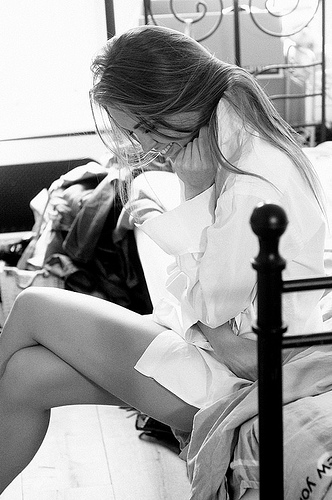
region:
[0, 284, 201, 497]
A woman's sexy legs crossed left over right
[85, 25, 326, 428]
Pretty woman sitting on bed looking down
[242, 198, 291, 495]
Black colored tubular bed post.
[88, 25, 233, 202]
Woman smiling while resting her hand on her face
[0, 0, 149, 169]
Bright outdoor light coming in through the window.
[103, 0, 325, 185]
Decorative frame of the bed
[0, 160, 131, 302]
Bunch of clothes lay in a heap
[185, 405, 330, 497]
New York printed bed sheets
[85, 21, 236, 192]
Lady with her hair falling onto her face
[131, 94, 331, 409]
Crisp white cotton button down shirt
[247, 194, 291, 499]
black metal post on the bed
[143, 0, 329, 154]
metal head board on the bed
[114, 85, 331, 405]
white shirt on the woman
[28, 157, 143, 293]
a basket full of clothes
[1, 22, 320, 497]
a woman sitting on the bed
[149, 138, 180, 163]
a smile on the woman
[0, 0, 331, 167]
windows next to the bed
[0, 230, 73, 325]
wicker basket full of clothes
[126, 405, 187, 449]
shoes next to the bed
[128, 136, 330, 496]
bed with white sheets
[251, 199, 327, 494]
bed is black metal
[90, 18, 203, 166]
woman is smiling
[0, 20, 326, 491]
woman is sittig on the bed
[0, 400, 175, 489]
floor is woden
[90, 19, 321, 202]
woman has long hair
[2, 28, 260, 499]
woman is caucasian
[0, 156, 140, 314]
pile of clothes spilling out clothes basket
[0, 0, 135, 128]
window letting bright light in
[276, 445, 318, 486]
New York on sheets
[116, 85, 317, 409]
woman wearing man's white shirt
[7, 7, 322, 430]
the picture is black and white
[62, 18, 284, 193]
the woman`s head is down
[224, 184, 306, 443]
the bed post is black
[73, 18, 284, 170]
the woman`s hair is brown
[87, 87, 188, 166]
the woman is smiling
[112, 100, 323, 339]
the shirt is white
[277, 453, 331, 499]
the letters are black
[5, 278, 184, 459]
the legs are crossed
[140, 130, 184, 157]
the woman`s teeth are showing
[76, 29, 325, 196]
the woman`s hair is long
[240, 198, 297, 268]
the round part of the bed post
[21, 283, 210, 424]
the woman's left thigh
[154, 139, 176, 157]
the teeth of the woman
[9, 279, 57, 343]
the woman's left knee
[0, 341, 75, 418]
the woman's right knee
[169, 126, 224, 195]
the woman's left hand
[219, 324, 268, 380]
the woman's right hand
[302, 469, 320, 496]
the letter "y" on the blanket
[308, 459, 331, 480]
the letter "w" on the blanket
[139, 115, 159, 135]
the woman's left eye